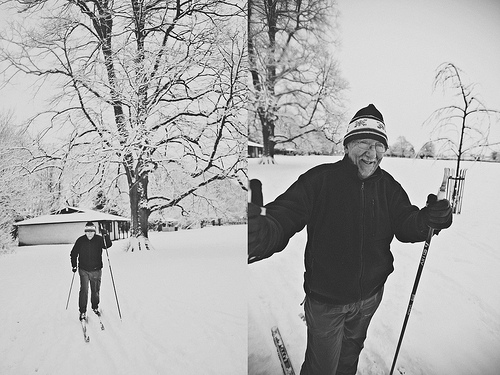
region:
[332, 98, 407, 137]
He has a hat on.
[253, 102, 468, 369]
He is holding a ski pole.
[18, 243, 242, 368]
The ground is snow covered.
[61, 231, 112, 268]
The man's jacket is black.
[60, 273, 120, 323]
He is wearing black pants.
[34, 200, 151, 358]
He is skiing.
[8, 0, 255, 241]
The tree is snow covered.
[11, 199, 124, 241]
The building is by the tree.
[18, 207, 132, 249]
The roof is snow covered.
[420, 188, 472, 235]
He is wearing gloves.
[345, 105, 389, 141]
a man's winter cap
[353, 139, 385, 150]
a man's eye glasses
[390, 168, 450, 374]
a man's left ski pole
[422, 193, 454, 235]
a man's left hand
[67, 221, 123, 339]
a man cross country skiing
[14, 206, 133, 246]
a house covered in snow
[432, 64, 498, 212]
a scrawny tree in the snow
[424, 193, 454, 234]
a man's winter glove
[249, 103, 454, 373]
a smiling man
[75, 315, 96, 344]
a man's right ski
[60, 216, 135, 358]
Older man skiing with cap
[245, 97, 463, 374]
Older man smiling while standing on skis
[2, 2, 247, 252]
Tall barren tree covered in snow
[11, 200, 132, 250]
Single story house with snow on roof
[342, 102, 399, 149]
Black cold weather cap with white band and snowflake design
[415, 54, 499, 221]
Small barren tree inside of metal ring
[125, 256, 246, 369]
Snow covered landscape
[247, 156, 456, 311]
Zipped up black fleece jacket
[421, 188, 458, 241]
Black skiing glove wrapped around ski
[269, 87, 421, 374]
Elderly man wearing glasses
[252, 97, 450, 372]
old snowboarder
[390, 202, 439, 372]
pole in the right hand of old man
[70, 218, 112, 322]
old snowboarder in left side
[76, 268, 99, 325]
pants of man in left side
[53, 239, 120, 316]
wo poles of snowboarder in left side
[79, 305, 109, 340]
two skis of snowboarder in left side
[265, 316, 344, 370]
two skis of snowboarder in right side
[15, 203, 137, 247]
white house in the back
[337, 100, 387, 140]
black and white balaclava of man in the right side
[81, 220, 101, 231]
black and white balaclava of man in the left side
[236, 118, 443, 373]
the man has glasses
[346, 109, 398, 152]
the marvin is black and white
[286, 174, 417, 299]
the sweater is black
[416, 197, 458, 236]
the gloves are black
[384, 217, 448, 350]
pole is on the snow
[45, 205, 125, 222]
snow is on the roof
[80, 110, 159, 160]
snow is on the trees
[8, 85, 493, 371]
the season is winter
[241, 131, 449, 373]
the oldman is smiling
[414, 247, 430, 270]
writing is on the pole